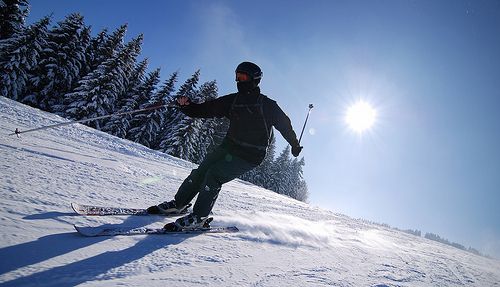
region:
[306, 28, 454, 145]
this is the sky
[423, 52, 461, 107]
the sky is blue in color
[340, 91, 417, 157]
this is the sun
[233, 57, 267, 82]
this is a helmet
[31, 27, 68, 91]
this is a tree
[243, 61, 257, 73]
the helmet is black in color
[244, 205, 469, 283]
this is the snow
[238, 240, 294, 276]
the snow is white in color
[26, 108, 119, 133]
the stick is long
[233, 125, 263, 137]
this is the jacket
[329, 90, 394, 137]
The bright sun in the sky.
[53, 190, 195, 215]
The left ski the skier is on.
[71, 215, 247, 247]
The right ski the skier is on.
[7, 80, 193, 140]
The ski pole in the skier's left hand.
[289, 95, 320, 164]
The ski pole in the skier's right hand.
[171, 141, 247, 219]
The pants the skier is wearing.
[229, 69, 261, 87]
The goggles the skier is wearing.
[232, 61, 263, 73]
The black helmet/hat the skier is wearing.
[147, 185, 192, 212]
The left ski boot of the skier.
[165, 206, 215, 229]
The right ski boot of the skier.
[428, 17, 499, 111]
The sky is blue.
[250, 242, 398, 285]
The snow is white.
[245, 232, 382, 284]
Snow is on the ground.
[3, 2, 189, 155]
Snow is on the trees.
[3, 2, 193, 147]
The trees are green.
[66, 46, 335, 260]
The person is skiing.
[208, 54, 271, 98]
The person is wearing goggles.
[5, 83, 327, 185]
The person is holding ski poles.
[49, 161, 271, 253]
The person is wearing skis.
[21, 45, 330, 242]
a person is skiing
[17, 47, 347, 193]
the person is holding ski poles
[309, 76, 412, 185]
the sun is shining bright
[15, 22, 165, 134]
the trees have snow on them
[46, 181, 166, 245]
the skis are covered with snow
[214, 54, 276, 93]
the man`s face is covered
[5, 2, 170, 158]
the trees are tall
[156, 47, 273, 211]
the person is wearing all black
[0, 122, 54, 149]
the tip of the pole is pointed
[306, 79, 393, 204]
the sun is white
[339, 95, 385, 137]
Sun shining in the sky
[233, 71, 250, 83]
Man wearing goggles over his eyes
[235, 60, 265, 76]
Man wearing a black helmet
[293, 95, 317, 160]
Ski pole in a man's left hand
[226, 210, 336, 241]
Powdery snow kicked up behind a skiing man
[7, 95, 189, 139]
Ski pole in front of a man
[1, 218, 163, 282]
Skiing man's shadow in the snow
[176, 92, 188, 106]
Exposed fingers on a man's left hand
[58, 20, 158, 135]
Snow covered pine trees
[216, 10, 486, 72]
Clear blue sky above a skier